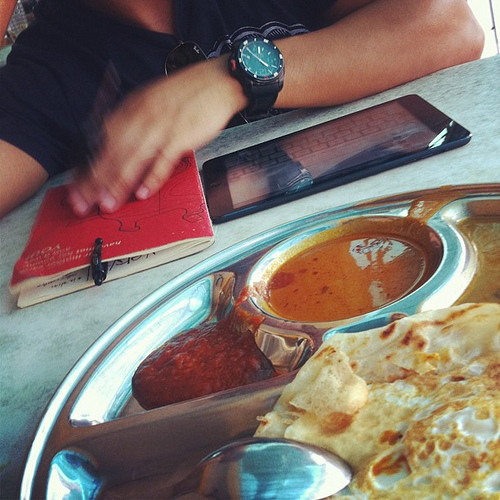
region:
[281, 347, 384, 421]
This is a piece pizza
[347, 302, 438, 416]
This is a piece pizza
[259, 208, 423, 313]
a tray with sauce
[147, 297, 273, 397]
a tray with sauce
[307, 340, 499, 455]
a tray with food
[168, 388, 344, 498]
a tray with spoon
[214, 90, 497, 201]
a tablet on table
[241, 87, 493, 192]
a table with tablet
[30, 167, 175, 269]
a book with pen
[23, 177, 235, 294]
the notebook is red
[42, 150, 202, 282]
the notebook is red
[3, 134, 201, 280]
the notebook is red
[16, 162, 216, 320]
the notebook is red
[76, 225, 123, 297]
a pen inside the notebook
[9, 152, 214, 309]
the book is red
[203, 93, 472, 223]
the tablet is black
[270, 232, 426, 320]
the sauce is brown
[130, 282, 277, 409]
the sauce is red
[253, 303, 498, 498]
the eggs are fried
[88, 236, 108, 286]
the pen is black